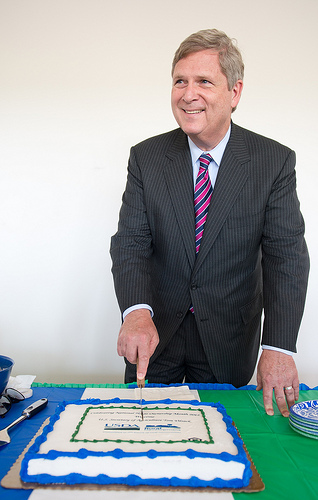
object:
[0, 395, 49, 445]
spatula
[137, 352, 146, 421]
knife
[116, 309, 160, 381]
hand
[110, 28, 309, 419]
man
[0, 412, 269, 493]
cardboard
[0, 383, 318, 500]
tablecloth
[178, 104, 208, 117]
smile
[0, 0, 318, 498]
room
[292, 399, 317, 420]
plates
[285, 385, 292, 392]
ring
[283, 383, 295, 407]
finger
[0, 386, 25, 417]
eyeglasses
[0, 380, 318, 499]
table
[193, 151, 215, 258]
striped tie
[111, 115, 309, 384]
suit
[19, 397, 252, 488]
cake